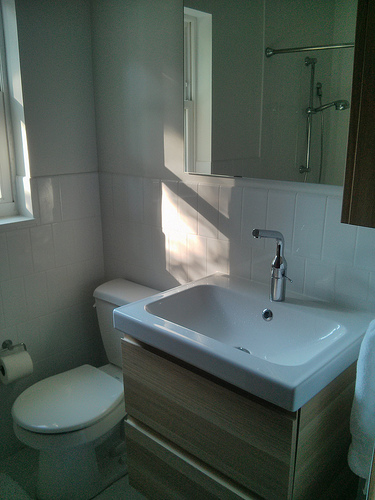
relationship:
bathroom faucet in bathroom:
[250, 225, 294, 304] [4, 0, 370, 498]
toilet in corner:
[9, 273, 169, 498] [57, 3, 137, 393]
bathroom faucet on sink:
[250, 225, 294, 304] [110, 274, 373, 410]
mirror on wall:
[175, 7, 352, 185] [91, 0, 373, 317]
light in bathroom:
[157, 180, 235, 286] [4, 0, 370, 498]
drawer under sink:
[119, 336, 296, 498] [110, 274, 373, 410]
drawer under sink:
[118, 416, 251, 498] [110, 274, 373, 410]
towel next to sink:
[347, 320, 372, 481] [110, 274, 373, 410]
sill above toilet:
[1, 201, 34, 223] [9, 273, 169, 498]